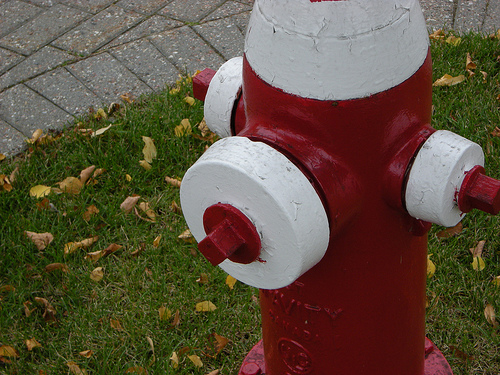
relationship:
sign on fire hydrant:
[260, 291, 342, 373] [178, 1, 499, 374]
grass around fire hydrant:
[2, 34, 497, 374] [178, 1, 499, 374]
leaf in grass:
[30, 231, 54, 254] [2, 34, 497, 374]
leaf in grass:
[29, 184, 51, 200] [2, 34, 497, 374]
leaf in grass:
[197, 300, 217, 312] [2, 34, 497, 374]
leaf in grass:
[433, 73, 468, 87] [2, 34, 497, 374]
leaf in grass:
[120, 197, 138, 216] [2, 34, 497, 374]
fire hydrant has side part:
[178, 1, 499, 374] [398, 130, 499, 227]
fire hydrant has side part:
[178, 1, 499, 374] [191, 57, 243, 135]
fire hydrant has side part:
[178, 1, 499, 374] [178, 132, 340, 293]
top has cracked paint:
[244, 0, 429, 100] [264, 11, 419, 47]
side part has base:
[398, 130, 499, 227] [407, 130, 485, 230]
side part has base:
[191, 57, 243, 135] [204, 57, 244, 136]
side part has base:
[178, 132, 340, 293] [177, 133, 328, 289]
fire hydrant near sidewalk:
[178, 1, 499, 374] [0, 0, 500, 157]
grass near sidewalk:
[2, 34, 497, 374] [0, 0, 500, 157]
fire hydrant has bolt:
[178, 1, 499, 374] [200, 205, 262, 266]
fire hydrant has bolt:
[178, 1, 499, 374] [458, 166, 499, 216]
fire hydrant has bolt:
[178, 1, 499, 374] [192, 65, 217, 103]